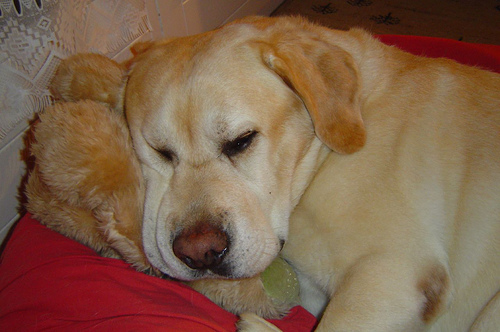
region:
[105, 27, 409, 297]
the dog looks sleepy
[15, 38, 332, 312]
the dog is laying on a stuffed animal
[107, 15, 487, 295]
the dog is pale tan in color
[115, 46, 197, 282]
the dog's face is squished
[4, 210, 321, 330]
red pillow under the dog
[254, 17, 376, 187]
the dog's ear is darker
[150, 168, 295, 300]
the dog's brown nose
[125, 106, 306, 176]
the dog's eyes are partially closed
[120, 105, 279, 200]
the dog's eyes are a dark color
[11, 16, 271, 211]
lace design behind the dog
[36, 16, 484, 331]
yellow dog sleeping on red bed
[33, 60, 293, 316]
stuffed animal dog is sleeping on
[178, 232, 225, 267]
pink nose of yellow dog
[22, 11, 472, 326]
red bed dog is sleeping on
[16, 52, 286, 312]
light colored teddy bear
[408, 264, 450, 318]
darker patch on dog's elbow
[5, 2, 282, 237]
wall dog's bed is leaning against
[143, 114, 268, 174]
closed eyes of yellow dog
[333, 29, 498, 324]
body of yellow dog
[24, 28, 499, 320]
dog resting his head on stuffed animal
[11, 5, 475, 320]
the dog is resting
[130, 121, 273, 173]
the eyes are half closed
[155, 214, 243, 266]
the nose is pink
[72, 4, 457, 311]
the dog is gold colored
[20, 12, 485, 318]
the cushion under the dog is red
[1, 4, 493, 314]
the dog is laying on a cushion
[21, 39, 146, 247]
the stuffed animal is tan colored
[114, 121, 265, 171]
the eyes are black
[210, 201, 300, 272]
the dog has whiskers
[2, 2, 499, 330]
The brown sleeping dog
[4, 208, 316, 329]
The red sheets on the left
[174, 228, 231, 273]
A brown dog nose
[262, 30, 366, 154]
The dog ear on the right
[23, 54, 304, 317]
The golden stuffed animal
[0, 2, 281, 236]
The white wall covers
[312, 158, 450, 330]
The dog limb with a brown spot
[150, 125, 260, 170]
The tight closed dog eyes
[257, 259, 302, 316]
The green foot of a stuffed animal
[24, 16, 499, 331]
A brown dog asleep by the stuffed animal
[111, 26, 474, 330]
the dog is laying down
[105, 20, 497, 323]
the dog is brown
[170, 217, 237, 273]
dog's nose is brown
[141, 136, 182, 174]
dog's eye is squished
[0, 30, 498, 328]
the blanket is red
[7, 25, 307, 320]
dog laying on stuffed animal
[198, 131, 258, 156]
dog's eye is black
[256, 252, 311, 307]
stuffed animal's foot is green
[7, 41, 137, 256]
the stuffed animal is brown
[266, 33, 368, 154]
dog's ear laying down